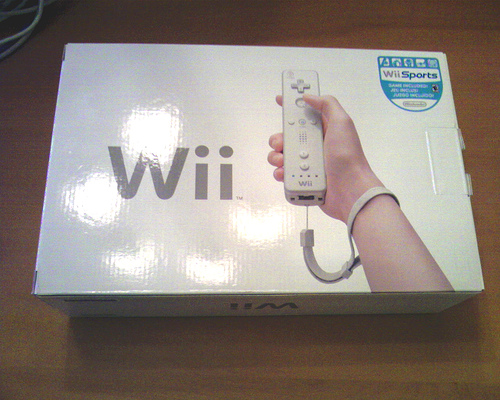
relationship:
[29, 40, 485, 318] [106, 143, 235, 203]
box of wii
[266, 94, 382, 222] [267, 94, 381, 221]
hand holding holding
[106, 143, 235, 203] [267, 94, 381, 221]
wii game holding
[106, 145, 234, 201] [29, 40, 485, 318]
symbol on box.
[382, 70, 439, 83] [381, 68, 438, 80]
wii sports symbol.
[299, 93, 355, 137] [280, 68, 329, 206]
thumb on wii.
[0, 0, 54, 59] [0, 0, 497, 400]
corner on picture.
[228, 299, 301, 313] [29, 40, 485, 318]
symbol on box.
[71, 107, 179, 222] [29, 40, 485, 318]
reflecting off box.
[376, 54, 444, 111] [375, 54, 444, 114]
blue wii label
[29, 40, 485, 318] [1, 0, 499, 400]
box on table.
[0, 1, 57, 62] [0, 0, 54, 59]
top left corner.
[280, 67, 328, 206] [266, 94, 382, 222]
controller in hand.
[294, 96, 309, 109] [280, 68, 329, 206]
circle on remote.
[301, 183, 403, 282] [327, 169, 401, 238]
strap around wrist.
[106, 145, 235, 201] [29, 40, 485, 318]
letters on box.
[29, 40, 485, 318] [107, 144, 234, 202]
box with game.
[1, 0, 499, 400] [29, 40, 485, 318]
table under box.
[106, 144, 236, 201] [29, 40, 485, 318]
logo on box.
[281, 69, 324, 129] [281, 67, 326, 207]
top of controller.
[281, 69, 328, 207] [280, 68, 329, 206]
white wii remote.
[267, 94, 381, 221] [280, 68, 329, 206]
holding white wii.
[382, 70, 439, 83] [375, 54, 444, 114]
wii sports label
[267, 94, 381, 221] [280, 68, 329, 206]
holds a wii.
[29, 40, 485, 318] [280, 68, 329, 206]
box for wii.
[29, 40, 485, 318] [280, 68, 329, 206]
box with wii.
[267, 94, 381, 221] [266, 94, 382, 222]
holding in hand.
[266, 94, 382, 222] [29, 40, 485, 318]
hand on box.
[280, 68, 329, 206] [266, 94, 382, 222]
remote in hand.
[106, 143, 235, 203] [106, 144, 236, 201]
wii trademarked logo.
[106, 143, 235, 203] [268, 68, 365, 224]
wii remote image.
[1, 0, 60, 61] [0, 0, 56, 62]
cables in background.